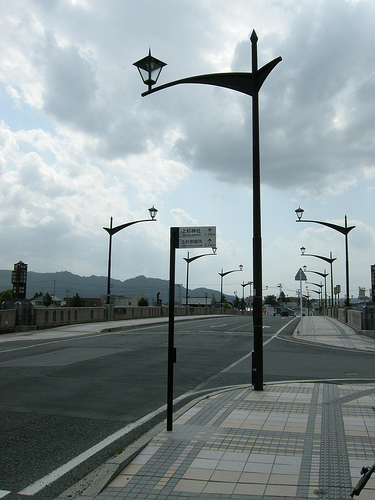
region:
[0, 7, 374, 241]
The sky is cloudy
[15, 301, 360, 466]
The street is empty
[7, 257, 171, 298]
Trees are in the background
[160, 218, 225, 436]
A sign is on a pole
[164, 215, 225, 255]
The sign is white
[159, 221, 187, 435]
The pole is black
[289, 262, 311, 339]
A back view of a sign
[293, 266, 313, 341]
The back view of the sign is gray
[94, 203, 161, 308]
The streetlight pole is black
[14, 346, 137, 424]
The street is dark gray in color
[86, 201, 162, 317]
Street light for improved vision at night.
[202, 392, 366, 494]
Stone sidewalks for easy pedestrian maneuvering.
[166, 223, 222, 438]
Street sign and pole for know location and direction.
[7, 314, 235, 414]
Intersection of two roads.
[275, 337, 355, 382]
Asphalt pavement for smooth vehicle travel.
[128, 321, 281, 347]
Crosswalk for pedestrians who want to cross the street.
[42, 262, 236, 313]
Mountains off in the distance.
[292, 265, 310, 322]
Traffic control sign.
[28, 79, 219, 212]
Mostly cloudy skies.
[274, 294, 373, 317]
Populated area on the other side of the bridge.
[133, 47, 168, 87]
a street lamp is off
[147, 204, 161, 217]
a street lamp is off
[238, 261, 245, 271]
a street lamp is off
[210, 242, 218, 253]
a street lamp is off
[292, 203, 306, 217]
a street lamp is off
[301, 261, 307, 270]
a street lamp is off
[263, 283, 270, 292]
a street lamp is off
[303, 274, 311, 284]
a street lamp is off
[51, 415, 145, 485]
a white line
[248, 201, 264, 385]
a pole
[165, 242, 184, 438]
a tell pole in the street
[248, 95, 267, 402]
a tell pole in the street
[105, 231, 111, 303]
a tell pole in the street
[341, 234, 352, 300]
a tell pole in the street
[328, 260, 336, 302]
a tell pole in the street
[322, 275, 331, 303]
a tell pole in the street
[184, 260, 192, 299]
a tell pole in the street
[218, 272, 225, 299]
a tell pole in the street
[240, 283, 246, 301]
a tell pole in the street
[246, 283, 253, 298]
a tell pole in the street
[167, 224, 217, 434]
a street sign on the pole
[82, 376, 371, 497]
the sidewalk next to the street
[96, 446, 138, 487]
a pushed up section of the curb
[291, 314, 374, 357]
another section of sidewwalk with a tiled pattern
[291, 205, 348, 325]
a line of street lights by the side of the road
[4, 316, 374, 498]
the street that the cars go down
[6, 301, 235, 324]
the fence on the side of the road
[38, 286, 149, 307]
buildings behind the fence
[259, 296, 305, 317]
houses at the end of the road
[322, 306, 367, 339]
the fence on the other side of the road